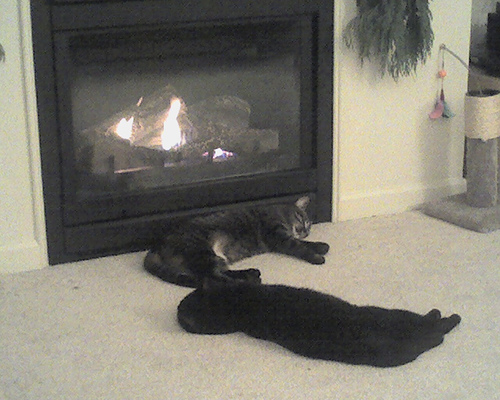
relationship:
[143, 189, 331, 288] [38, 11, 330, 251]
cat warming up by fireplace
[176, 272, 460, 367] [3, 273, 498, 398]
cat on floor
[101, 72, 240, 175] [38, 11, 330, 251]
fire in fireplace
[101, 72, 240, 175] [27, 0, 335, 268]
fire in fire place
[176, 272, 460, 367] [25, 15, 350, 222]
cat in front of fireplace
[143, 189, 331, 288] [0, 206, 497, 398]
cat are on carpet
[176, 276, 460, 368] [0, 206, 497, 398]
cat are on carpet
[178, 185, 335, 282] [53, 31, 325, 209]
cat by fireplace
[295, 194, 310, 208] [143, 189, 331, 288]
ear on cat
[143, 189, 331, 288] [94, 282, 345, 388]
cat laying on carpet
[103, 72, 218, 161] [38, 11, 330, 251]
fire in fireplace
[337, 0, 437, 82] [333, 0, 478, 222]
fern on wall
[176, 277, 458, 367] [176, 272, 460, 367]
fur on cat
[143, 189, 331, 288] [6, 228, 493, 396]
cat laying on floor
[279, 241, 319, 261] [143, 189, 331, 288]
leg on cat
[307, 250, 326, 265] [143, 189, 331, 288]
left paw on cat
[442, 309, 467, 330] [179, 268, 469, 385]
paw on cat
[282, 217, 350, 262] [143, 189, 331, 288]
left paw on cat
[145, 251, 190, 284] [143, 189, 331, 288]
tail on cat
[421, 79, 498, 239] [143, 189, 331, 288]
stand for cat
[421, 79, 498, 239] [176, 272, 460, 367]
stand for cat